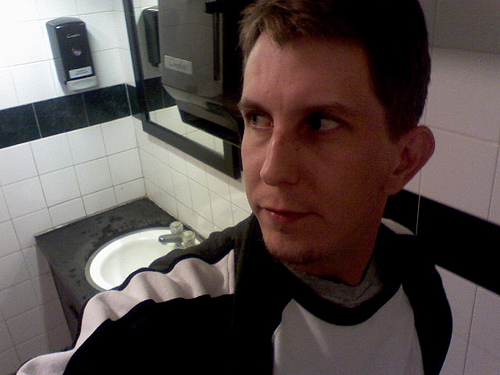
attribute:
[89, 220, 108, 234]
water — splashes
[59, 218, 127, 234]
water — splashes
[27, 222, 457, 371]
top — white, black , man's 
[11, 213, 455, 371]
shirt — BLACK , WHITE , striped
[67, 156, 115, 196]
tile — white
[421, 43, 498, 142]
tile — white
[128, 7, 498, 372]
wall — white, tile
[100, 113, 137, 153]
tile — white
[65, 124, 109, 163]
tile — white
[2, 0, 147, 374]
wall — white, tile, tiled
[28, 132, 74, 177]
tile — white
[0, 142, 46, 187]
tile — white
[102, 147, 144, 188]
tile — white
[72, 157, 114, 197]
tile — white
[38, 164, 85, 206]
tile — white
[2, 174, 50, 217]
tile — white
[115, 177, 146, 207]
tile — white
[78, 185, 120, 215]
tile — white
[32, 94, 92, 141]
tile — black